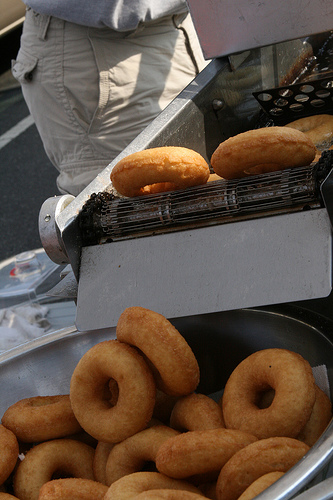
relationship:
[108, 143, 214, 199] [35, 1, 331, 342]
donut exits fryer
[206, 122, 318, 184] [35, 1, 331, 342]
donut exits fryer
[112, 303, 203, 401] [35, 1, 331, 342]
donut exits fryer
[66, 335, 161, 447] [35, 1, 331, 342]
donut exits fryer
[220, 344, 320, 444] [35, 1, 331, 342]
donut exits fryer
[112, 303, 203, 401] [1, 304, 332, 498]
donut in bowl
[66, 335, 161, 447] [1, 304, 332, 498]
donut in bowl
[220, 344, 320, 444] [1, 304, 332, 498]
donut in bowl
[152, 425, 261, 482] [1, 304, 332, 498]
donut in bowl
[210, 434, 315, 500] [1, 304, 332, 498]
donut in bowl